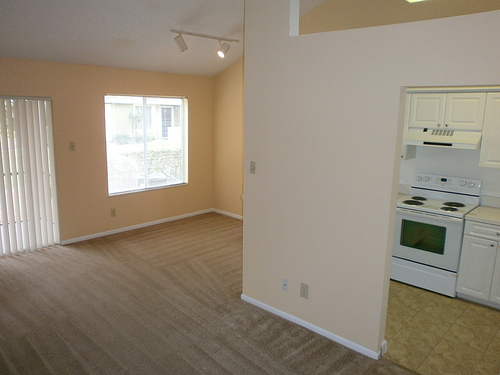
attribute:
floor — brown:
[2, 214, 379, 374]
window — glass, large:
[105, 96, 190, 195]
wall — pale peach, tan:
[53, 68, 247, 243]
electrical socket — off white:
[299, 281, 310, 300]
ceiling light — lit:
[218, 43, 233, 60]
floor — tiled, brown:
[391, 282, 497, 371]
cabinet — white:
[411, 94, 480, 133]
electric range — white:
[457, 180, 476, 190]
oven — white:
[389, 209, 464, 294]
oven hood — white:
[388, 252, 453, 298]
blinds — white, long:
[3, 96, 59, 254]